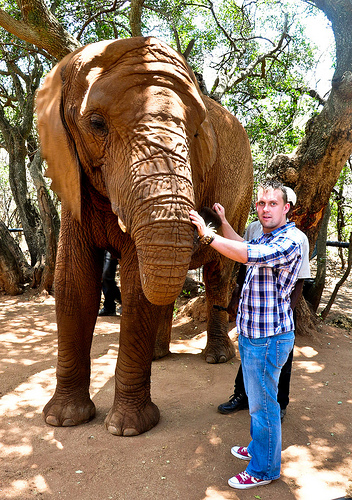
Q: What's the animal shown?
A: Elephant.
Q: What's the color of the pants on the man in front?
A: Blue.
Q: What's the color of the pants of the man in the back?
A: Black.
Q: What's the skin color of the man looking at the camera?
A: White.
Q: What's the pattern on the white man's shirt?
A: Plaid.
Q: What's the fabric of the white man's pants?
A: Denim.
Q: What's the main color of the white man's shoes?
A: Red.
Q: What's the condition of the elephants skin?
A: Wrinkled.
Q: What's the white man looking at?
A: Camera.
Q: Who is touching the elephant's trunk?
A: The man wearing jeans.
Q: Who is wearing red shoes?
A: The man touching the elephant.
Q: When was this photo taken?
A: During the daytime.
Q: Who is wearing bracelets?
A: The man in the plaid shirt.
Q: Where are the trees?
A: Behind the elephant.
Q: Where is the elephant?
A: Standing next to the people.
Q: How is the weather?
A: Sunny and clear.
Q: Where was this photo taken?
A: In a wildlife enclosure.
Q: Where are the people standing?
A: Next to the elephant.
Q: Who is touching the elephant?
A: The man with the bracelets and plaid shirt.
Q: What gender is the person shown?
A: Male.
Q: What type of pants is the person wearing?
A: Jeans.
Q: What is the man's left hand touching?
A: Elephant trunk.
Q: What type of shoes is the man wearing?
A: Tennis shoes.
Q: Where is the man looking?
A: Toward the camera.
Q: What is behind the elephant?
A: Trees.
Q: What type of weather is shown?
A: Clear and sunny.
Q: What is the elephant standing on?
A: Dirt.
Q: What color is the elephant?
A: Brown.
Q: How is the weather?
A: Sunny.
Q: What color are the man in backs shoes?
A: Black.